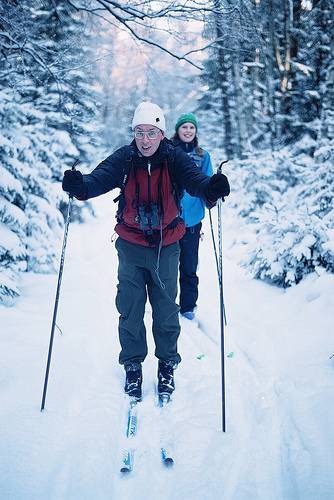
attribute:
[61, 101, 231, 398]
skier — male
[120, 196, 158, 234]
binoculars — pair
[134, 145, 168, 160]
neck — skier's